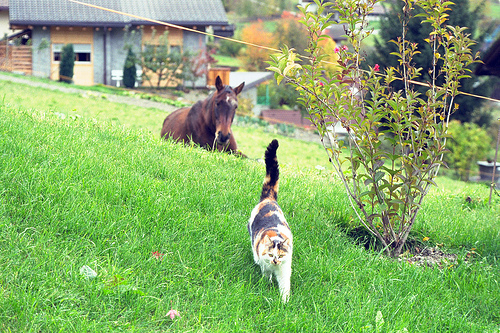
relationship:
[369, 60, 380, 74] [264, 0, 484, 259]
flower on shrub/bush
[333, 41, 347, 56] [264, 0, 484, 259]
flower on shrub/bush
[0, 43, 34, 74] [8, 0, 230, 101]
fence attached to house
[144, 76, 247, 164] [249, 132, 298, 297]
horse watching cat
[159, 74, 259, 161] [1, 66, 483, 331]
horse laying in grass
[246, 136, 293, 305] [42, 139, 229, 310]
cat walking in grass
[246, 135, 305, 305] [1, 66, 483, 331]
cat walking through grass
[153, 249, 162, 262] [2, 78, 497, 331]
flower in lawn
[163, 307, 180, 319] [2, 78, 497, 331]
flower in lawn